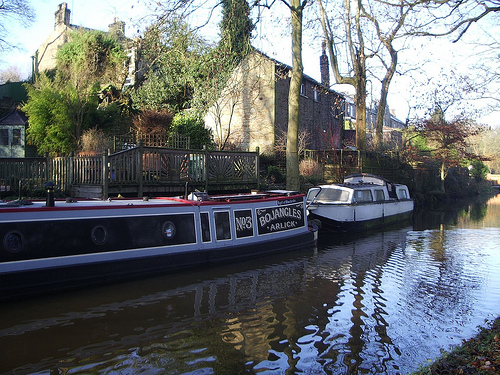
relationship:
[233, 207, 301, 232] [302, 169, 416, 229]
name on side of boat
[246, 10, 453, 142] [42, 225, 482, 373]
trees reflection on river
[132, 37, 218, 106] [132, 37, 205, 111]
leaves have leaves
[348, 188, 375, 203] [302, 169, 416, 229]
window on boat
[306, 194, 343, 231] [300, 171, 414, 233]
front of boat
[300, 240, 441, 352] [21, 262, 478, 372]
light reflecting on surface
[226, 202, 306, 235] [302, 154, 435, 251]
name on boat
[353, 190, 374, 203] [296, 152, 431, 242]
window in boat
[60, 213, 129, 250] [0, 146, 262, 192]
circular window in dock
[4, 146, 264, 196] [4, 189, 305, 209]
fence on dock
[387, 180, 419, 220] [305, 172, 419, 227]
back of boat